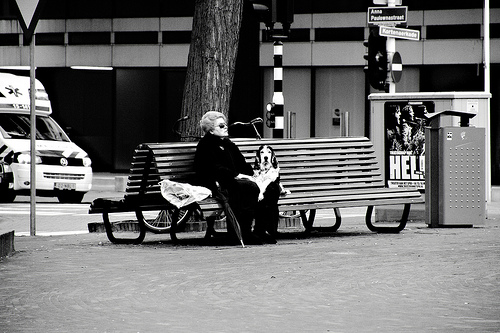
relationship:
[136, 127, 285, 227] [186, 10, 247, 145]
bicycle leaning against tree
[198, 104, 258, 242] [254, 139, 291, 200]
woman and dog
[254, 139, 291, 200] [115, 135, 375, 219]
dog on bench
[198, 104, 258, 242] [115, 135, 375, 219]
woman on bench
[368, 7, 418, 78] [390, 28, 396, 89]
signs on pole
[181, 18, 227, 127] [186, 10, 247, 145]
trunk of tree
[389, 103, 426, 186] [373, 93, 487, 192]
poster on service box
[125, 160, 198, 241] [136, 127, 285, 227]
wheel of bicycle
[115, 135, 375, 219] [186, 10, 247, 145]
bench near tree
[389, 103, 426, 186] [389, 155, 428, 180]
poster says help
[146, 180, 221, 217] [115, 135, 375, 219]
bag on bench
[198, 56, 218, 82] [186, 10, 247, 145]
bark of tree